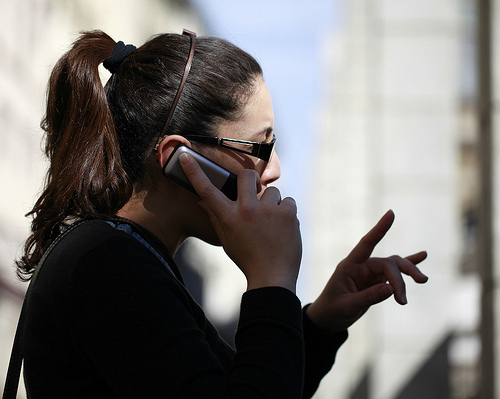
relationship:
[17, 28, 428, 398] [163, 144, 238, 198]
lady using phone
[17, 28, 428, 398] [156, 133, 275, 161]
lady wearing spectacles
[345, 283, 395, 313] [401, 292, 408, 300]
finger has nail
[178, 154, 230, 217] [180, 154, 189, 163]
finger has nail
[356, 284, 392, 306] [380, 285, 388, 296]
finger has nail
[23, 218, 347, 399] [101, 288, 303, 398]
blouse has sleeve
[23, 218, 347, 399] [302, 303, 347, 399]
blouse has sleeve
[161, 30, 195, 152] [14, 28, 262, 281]
band over hair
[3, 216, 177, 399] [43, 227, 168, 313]
strap over shoulder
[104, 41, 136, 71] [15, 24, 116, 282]
holder over ponytail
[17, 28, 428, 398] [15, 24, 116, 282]
lady wearing ponytail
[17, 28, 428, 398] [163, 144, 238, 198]
lady has phone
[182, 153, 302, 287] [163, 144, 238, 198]
hand holds phone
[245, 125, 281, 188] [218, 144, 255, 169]
face has shadow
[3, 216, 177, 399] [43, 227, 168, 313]
strap on shoulder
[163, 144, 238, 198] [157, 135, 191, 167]
phone against ear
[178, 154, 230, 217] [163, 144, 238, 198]
finger on phone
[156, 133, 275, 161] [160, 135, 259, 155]
spectacles have side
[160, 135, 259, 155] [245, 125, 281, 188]
side on face